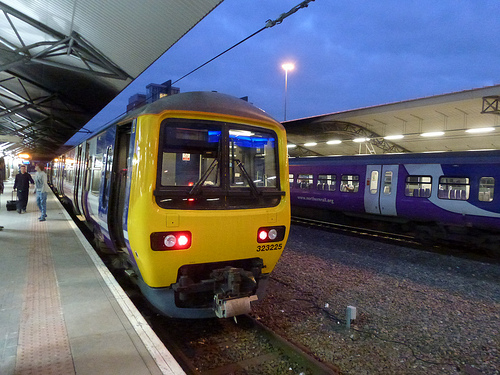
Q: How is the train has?
A: Empty.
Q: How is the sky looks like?
A: Blue.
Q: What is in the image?
A: Train.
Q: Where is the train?
A: Track.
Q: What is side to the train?
A: Platform.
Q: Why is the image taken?
A: Remembrance.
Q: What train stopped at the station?
A: Modern train.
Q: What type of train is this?
A: Passenger.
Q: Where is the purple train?
A: Right.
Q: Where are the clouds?
A: In the sky.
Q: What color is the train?
A: Yellow.